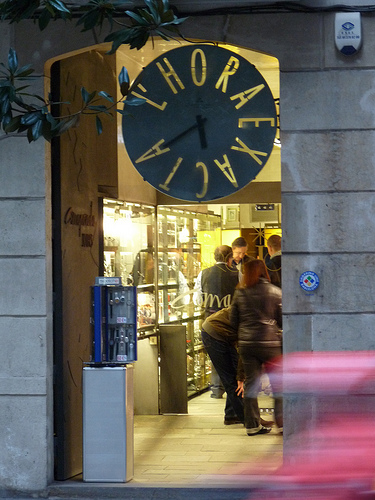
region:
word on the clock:
[156, 56, 277, 172]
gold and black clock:
[152, 64, 240, 165]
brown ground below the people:
[187, 425, 222, 455]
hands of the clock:
[170, 109, 215, 153]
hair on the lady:
[232, 251, 280, 291]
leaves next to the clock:
[20, 84, 88, 135]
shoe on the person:
[246, 419, 269, 438]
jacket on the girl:
[226, 280, 280, 332]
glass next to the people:
[111, 221, 200, 301]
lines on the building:
[292, 64, 364, 225]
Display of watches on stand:
[76, 269, 160, 365]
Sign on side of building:
[294, 263, 328, 304]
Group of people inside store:
[193, 236, 286, 427]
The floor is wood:
[166, 412, 244, 485]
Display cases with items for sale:
[101, 199, 199, 287]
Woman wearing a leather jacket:
[233, 274, 284, 345]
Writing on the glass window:
[143, 273, 244, 322]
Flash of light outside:
[251, 351, 367, 496]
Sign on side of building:
[55, 203, 102, 256]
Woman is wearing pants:
[229, 343, 303, 433]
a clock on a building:
[123, 45, 277, 199]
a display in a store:
[89, 277, 140, 363]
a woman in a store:
[226, 258, 284, 434]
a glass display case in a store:
[103, 198, 220, 326]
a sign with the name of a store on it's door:
[59, 203, 104, 252]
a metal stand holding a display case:
[75, 361, 140, 483]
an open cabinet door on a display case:
[158, 324, 190, 417]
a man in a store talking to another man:
[196, 245, 233, 307]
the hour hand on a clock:
[193, 113, 208, 146]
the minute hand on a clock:
[160, 119, 205, 150]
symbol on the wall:
[286, 267, 327, 301]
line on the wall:
[325, 299, 358, 338]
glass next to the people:
[147, 227, 198, 278]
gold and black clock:
[134, 48, 264, 188]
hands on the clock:
[169, 107, 215, 152]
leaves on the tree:
[46, 88, 101, 144]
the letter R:
[207, 51, 252, 102]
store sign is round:
[137, 43, 311, 180]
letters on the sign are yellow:
[131, 52, 286, 223]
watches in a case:
[88, 280, 145, 381]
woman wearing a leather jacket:
[239, 277, 288, 348]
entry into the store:
[49, 52, 270, 399]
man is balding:
[206, 241, 237, 254]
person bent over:
[178, 286, 272, 439]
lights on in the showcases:
[98, 197, 157, 242]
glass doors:
[166, 217, 205, 317]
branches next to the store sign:
[40, 7, 257, 151]